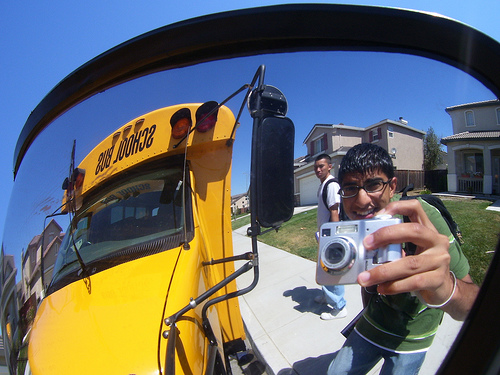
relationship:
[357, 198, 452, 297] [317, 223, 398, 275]
hand holding camera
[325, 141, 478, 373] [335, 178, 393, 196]
guy wearing glasses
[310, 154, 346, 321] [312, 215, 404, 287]
guy holding camera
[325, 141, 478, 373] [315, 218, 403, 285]
guy holding camera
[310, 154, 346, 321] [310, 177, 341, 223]
guy wearing white shirt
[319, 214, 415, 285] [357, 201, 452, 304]
camera in hand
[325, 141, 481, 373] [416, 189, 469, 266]
guy wears backpack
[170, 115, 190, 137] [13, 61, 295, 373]
headlight on bus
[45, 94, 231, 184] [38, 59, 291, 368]
headlight on bus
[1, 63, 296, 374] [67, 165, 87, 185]
bus has front headlight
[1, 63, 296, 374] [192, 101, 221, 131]
bus has headlight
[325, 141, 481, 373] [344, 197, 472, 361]
guy wears shirt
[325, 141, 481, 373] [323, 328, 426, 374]
guy wears blue jeans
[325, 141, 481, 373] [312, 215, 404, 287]
guy holds camera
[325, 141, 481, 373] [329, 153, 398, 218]
guy has head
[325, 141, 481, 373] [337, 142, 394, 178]
guy has hair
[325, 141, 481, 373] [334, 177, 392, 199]
guy has glasses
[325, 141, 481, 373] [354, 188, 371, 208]
guy has nose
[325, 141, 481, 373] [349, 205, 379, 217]
guy has mouth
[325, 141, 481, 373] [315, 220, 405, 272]
guy hold camera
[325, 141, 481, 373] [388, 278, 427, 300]
guy has finger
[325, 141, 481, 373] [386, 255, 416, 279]
guy has finger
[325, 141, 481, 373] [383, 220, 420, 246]
guy has finger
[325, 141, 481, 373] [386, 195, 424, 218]
guy has finger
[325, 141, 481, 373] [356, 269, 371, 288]
guy has finger nail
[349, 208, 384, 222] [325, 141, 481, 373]
teeth of guy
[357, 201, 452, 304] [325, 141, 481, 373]
hand of guy